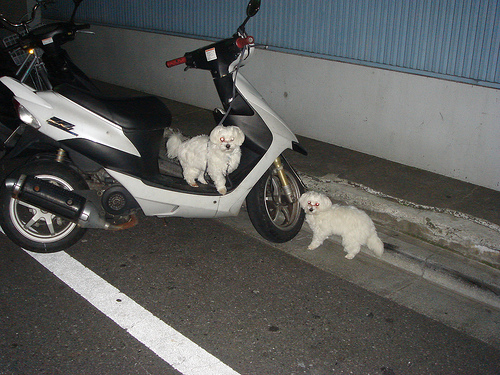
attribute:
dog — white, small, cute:
[164, 127, 242, 196]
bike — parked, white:
[2, 2, 301, 252]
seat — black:
[57, 84, 170, 135]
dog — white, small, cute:
[298, 194, 385, 259]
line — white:
[1, 225, 244, 374]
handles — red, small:
[164, 36, 256, 70]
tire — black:
[248, 165, 303, 243]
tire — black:
[4, 164, 86, 252]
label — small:
[46, 110, 79, 141]